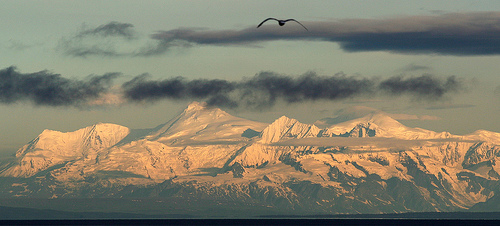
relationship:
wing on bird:
[257, 15, 281, 31] [264, 17, 301, 29]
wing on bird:
[281, 16, 309, 35] [264, 17, 301, 29]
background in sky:
[337, 0, 500, 60] [0, 0, 497, 132]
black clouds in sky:
[0, 64, 90, 111] [0, 0, 497, 132]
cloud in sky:
[70, 19, 136, 57] [0, 0, 497, 132]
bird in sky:
[256, 17, 310, 31] [2, 0, 491, 117]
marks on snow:
[221, 150, 387, 210] [195, 99, 476, 192]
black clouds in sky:
[0, 64, 90, 111] [4, 0, 499, 149]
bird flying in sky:
[256, 17, 310, 31] [37, 21, 242, 92]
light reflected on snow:
[7, 100, 494, 188] [382, 122, 433, 142]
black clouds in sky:
[0, 64, 90, 111] [163, 9, 246, 90]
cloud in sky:
[149, 21, 264, 50] [4, 0, 499, 149]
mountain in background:
[322, 109, 409, 140] [1, 9, 493, 139]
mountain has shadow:
[12, 95, 498, 211] [239, 122, 259, 138]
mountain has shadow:
[91, 138, 181, 199] [87, 168, 154, 182]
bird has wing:
[256, 17, 310, 31] [286, 16, 313, 36]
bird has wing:
[256, 17, 310, 31] [251, 13, 272, 33]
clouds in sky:
[111, 10, 442, 115] [4, 0, 499, 149]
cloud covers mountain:
[391, 110, 440, 122] [14, 105, 268, 197]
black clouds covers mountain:
[0, 64, 90, 111] [198, 111, 495, 222]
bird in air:
[256, 17, 310, 31] [0, 2, 494, 156]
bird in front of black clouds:
[251, 14, 310, 31] [0, 17, 500, 114]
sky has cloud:
[4, 0, 499, 149] [0, 64, 455, 108]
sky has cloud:
[4, 0, 499, 149] [78, 10, 498, 61]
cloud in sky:
[143, 7, 410, 68] [28, 27, 454, 182]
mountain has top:
[149, 97, 274, 145] [172, 95, 218, 123]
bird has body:
[256, 17, 310, 31] [275, 15, 290, 33]